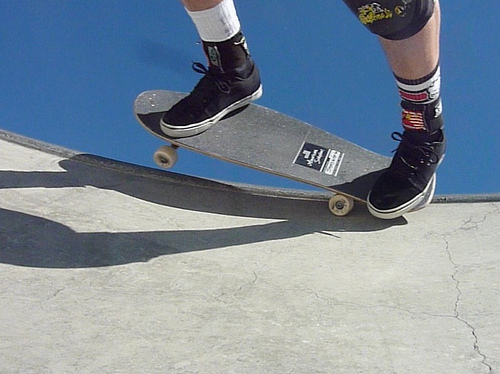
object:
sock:
[185, 0, 241, 45]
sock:
[390, 60, 445, 136]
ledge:
[0, 124, 498, 204]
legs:
[343, 0, 442, 135]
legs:
[181, 1, 254, 77]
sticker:
[292, 140, 349, 179]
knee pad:
[341, 0, 435, 43]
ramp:
[0, 125, 499, 373]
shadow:
[0, 151, 415, 271]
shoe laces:
[184, 59, 241, 95]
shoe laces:
[389, 130, 441, 166]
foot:
[364, 131, 451, 221]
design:
[301, 148, 313, 160]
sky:
[0, 0, 499, 196]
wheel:
[326, 193, 355, 217]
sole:
[159, 63, 267, 138]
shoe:
[366, 117, 452, 219]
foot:
[156, 57, 261, 140]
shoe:
[156, 57, 262, 140]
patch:
[457, 216, 481, 232]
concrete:
[0, 127, 496, 372]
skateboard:
[134, 86, 443, 215]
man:
[155, 0, 451, 220]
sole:
[367, 139, 454, 220]